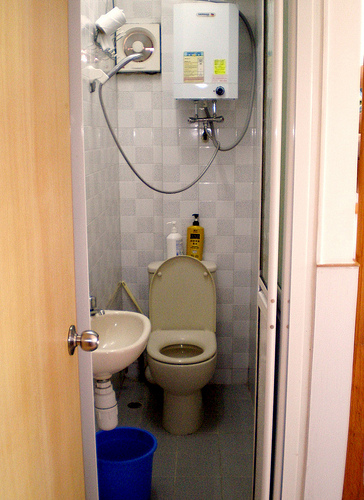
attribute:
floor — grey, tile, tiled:
[105, 380, 258, 495]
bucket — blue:
[97, 429, 153, 495]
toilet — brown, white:
[135, 248, 221, 438]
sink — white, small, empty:
[72, 303, 168, 429]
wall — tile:
[115, 12, 262, 275]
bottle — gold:
[188, 211, 207, 261]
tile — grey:
[127, 94, 172, 168]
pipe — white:
[91, 365, 125, 440]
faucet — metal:
[83, 283, 114, 325]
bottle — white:
[158, 215, 186, 270]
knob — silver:
[71, 319, 100, 362]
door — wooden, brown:
[9, 13, 99, 490]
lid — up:
[154, 251, 213, 332]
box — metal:
[172, 7, 238, 100]